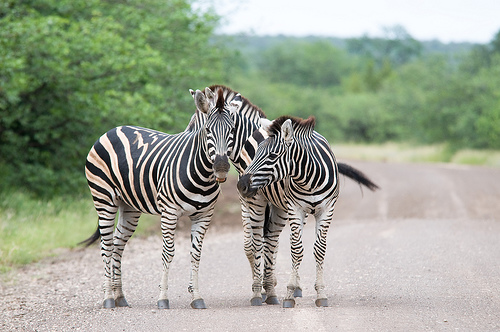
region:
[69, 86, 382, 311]
three black and white striped zebras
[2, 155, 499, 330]
gravel road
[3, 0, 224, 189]
tall bushy green trees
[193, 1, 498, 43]
blue and white sky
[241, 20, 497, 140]
a stand of green trees in the background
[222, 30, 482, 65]
tree covered hill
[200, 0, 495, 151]
the background is blurred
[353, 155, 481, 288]
tracks in the road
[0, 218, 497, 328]
gray colored gravel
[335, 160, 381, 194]
zebra's tail is black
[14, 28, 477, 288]
zebras on a road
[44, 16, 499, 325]
zebras on a street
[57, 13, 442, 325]
three zebras on a road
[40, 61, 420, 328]
three zebras on a street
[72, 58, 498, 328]
black and white zebras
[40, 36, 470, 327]
three black and white zebras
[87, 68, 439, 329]
black and white zebras on a road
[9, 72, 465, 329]
three black and white zebras on road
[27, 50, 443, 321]
black and white zebras on a street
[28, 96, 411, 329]
three black and white zebras on a street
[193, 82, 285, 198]
Two zebra faces near each other.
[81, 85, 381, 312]
Three zebras standing on the ground.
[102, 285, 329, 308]
Nine animal hooves touching the ground.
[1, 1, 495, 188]
Green vegetation is out of focus.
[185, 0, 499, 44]
The sky is light and gray.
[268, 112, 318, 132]
Zebra mane is black on top.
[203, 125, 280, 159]
Three zebra eyes are open.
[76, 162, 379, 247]
Two zebra tail ends are black.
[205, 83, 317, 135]
Three zebra manes near each other.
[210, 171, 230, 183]
Pink tongue below a animal lip.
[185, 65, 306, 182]
the head of a zebra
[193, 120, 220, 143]
the eye of a zebra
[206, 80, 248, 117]
the main of a zebra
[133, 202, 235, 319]
the front legs of a zebra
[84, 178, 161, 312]
the back legs of a zebra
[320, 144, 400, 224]
the tail of a zebra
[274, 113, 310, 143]
the ear of a zebra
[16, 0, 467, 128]
a wooded area behind some zebras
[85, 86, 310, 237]
white and black stripes on a zebra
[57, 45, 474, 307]
three zebras standing together